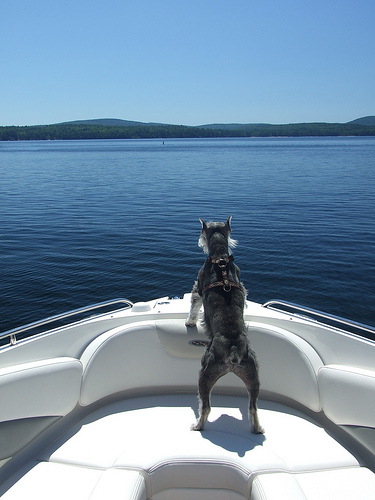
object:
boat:
[1, 285, 374, 499]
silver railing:
[0, 293, 141, 352]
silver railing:
[260, 296, 374, 339]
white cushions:
[0, 321, 373, 498]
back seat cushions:
[1, 316, 374, 434]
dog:
[184, 214, 268, 437]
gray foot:
[191, 421, 211, 433]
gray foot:
[250, 425, 264, 438]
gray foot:
[184, 311, 200, 328]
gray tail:
[222, 330, 254, 366]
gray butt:
[209, 330, 251, 361]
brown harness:
[197, 253, 250, 295]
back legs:
[235, 373, 269, 439]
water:
[1, 136, 373, 327]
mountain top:
[0, 115, 375, 141]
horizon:
[1, 113, 374, 141]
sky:
[0, 2, 374, 113]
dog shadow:
[189, 401, 267, 459]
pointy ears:
[223, 213, 237, 231]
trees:
[10, 124, 17, 137]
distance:
[4, 124, 371, 137]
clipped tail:
[228, 320, 252, 369]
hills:
[68, 116, 374, 126]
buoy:
[158, 136, 167, 146]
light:
[2, 143, 370, 367]